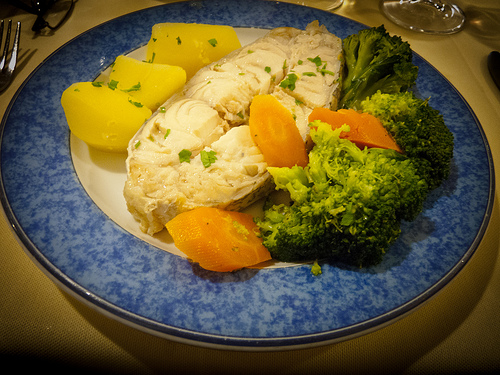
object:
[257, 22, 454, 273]
broccoli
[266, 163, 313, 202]
stalk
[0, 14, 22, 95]
fork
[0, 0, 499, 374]
table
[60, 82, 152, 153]
yellow veggies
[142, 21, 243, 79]
potato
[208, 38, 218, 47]
parsley flake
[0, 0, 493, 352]
blue plate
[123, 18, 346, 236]
fish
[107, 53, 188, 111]
potatoes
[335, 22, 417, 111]
spear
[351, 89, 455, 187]
spear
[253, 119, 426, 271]
spear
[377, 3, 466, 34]
clear glass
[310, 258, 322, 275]
crumb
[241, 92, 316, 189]
carrot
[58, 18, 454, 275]
food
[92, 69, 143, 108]
herbs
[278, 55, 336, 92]
herbs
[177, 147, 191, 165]
herbs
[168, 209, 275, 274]
carrot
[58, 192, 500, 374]
shadow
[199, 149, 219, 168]
chives